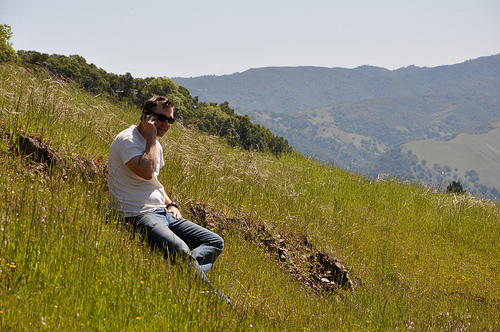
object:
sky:
[234, 5, 355, 53]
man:
[107, 97, 236, 318]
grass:
[28, 233, 124, 305]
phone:
[142, 111, 156, 126]